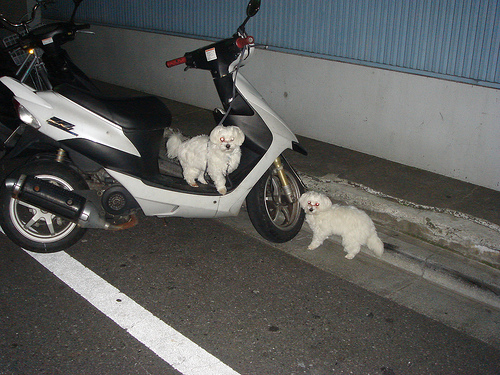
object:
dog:
[164, 124, 244, 196]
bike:
[2, 2, 311, 255]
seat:
[57, 84, 159, 131]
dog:
[298, 188, 390, 264]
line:
[21, 249, 241, 374]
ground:
[2, 78, 500, 375]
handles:
[164, 57, 189, 69]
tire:
[243, 165, 310, 245]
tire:
[4, 161, 92, 253]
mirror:
[245, 0, 263, 18]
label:
[46, 110, 79, 141]